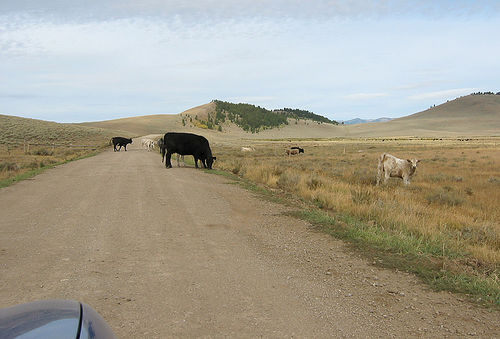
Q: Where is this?
A: This is at the road.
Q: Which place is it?
A: It is a road.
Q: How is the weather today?
A: It is cloudy.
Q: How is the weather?
A: It is cloudy.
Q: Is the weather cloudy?
A: Yes, it is cloudy.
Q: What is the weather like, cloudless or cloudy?
A: It is cloudy.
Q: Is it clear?
A: No, it is cloudy.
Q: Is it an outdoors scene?
A: Yes, it is outdoors.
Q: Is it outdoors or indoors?
A: It is outdoors.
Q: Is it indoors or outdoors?
A: It is outdoors.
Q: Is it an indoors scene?
A: No, it is outdoors.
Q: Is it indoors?
A: No, it is outdoors.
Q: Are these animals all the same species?
A: Yes, all the animals are cows.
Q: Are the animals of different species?
A: No, all the animals are cows.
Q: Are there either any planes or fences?
A: No, there are no fences or planes.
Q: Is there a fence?
A: No, there are no fences.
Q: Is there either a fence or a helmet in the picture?
A: No, there are no fences or helmets.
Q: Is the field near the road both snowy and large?
A: No, the field is large but grassy.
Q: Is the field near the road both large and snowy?
A: No, the field is large but grassy.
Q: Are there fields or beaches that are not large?
A: No, there is a field but it is large.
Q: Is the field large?
A: Yes, the field is large.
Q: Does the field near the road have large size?
A: Yes, the field is large.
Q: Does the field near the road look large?
A: Yes, the field is large.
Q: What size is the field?
A: The field is large.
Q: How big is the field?
A: The field is large.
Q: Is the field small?
A: No, the field is large.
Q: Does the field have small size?
A: No, the field is large.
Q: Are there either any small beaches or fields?
A: No, there is a field but it is large.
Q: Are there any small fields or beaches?
A: No, there is a field but it is large.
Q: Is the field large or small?
A: The field is large.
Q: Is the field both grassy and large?
A: Yes, the field is grassy and large.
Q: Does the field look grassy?
A: Yes, the field is grassy.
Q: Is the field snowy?
A: No, the field is grassy.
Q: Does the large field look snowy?
A: No, the field is grassy.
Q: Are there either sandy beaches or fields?
A: No, there is a field but it is grassy.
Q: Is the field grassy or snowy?
A: The field is grassy.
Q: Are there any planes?
A: No, there are no planes.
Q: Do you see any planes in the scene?
A: No, there are no planes.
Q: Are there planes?
A: No, there are no planes.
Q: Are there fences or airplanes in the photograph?
A: No, there are no airplanes or fences.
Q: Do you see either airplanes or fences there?
A: No, there are no airplanes or fences.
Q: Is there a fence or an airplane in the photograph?
A: No, there are no airplanes or fences.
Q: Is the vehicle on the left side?
A: Yes, the vehicle is on the left of the image.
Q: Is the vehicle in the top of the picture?
A: No, the vehicle is in the bottom of the image.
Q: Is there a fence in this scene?
A: No, there are no fences.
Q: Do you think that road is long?
A: Yes, the road is long.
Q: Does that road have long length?
A: Yes, the road is long.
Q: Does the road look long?
A: Yes, the road is long.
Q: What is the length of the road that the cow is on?
A: The road is long.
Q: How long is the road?
A: The road is long.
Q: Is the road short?
A: No, the road is long.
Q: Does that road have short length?
A: No, the road is long.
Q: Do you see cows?
A: Yes, there is a cow.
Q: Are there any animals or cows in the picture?
A: Yes, there is a cow.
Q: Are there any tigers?
A: No, there are no tigers.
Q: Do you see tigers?
A: No, there are no tigers.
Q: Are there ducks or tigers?
A: No, there are no tigers or ducks.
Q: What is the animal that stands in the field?
A: The animal is a cow.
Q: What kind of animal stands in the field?
A: The animal is a cow.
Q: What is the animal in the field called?
A: The animal is a cow.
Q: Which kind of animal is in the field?
A: The animal is a cow.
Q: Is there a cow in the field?
A: Yes, there is a cow in the field.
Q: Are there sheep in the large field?
A: No, there is a cow in the field.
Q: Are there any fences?
A: No, there are no fences.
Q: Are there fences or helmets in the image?
A: No, there are no fences or helmets.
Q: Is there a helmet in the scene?
A: No, there are no helmets.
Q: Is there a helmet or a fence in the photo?
A: No, there are no helmets or fences.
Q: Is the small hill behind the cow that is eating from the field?
A: Yes, the hill is behind the cow.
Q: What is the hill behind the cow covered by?
A: The hill is covered by the forest.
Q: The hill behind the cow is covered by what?
A: The hill is covered by the forest.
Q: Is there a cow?
A: Yes, there is a cow.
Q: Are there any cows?
A: Yes, there is a cow.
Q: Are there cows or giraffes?
A: Yes, there is a cow.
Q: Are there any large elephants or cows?
A: Yes, there is a large cow.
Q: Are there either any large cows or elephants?
A: Yes, there is a large cow.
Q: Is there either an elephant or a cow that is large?
A: Yes, the cow is large.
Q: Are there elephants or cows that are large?
A: Yes, the cow is large.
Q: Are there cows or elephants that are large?
A: Yes, the cow is large.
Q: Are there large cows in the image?
A: Yes, there is a large cow.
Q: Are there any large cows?
A: Yes, there is a large cow.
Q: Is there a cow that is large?
A: Yes, there is a cow that is large.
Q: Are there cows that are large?
A: Yes, there is a cow that is large.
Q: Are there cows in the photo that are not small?
A: Yes, there is a large cow.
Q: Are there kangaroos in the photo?
A: No, there are no kangaroos.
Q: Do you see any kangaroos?
A: No, there are no kangaroos.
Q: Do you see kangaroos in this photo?
A: No, there are no kangaroos.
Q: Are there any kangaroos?
A: No, there are no kangaroos.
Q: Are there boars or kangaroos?
A: No, there are no kangaroos or boars.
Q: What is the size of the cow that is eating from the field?
A: The cow is large.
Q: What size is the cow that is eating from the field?
A: The cow is large.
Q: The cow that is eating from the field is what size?
A: The cow is large.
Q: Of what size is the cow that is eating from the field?
A: The cow is large.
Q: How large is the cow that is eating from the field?
A: The cow is large.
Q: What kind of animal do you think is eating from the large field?
A: The animal is a cow.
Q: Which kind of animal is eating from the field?
A: The animal is a cow.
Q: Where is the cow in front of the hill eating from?
A: The cow is eating from the field.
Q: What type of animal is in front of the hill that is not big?
A: The animal is a cow.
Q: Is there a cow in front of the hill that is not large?
A: Yes, there is a cow in front of the hill.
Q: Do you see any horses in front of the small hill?
A: No, there is a cow in front of the hill.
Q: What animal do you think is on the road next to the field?
A: The animal is a cow.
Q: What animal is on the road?
A: The animal is a cow.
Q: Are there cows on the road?
A: Yes, there is a cow on the road.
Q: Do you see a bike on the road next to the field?
A: No, there is a cow on the road.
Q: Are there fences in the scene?
A: No, there are no fences.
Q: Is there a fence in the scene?
A: No, there are no fences.